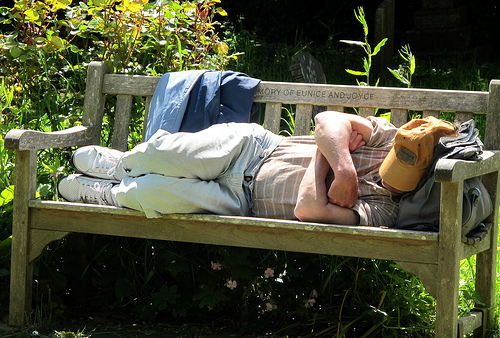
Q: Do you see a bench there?
A: Yes, there is a bench.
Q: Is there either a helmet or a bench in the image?
A: Yes, there is a bench.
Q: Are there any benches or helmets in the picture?
A: Yes, there is a bench.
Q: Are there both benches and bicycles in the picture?
A: No, there is a bench but no bicycles.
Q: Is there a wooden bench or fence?
A: Yes, there is a wood bench.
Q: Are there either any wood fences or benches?
A: Yes, there is a wood bench.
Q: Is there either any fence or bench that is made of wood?
A: Yes, the bench is made of wood.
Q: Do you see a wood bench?
A: Yes, there is a wood bench.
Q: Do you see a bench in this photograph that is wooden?
A: Yes, there is a bench that is wooden.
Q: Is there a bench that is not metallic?
A: Yes, there is a wooden bench.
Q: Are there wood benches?
A: Yes, there is a bench that is made of wood.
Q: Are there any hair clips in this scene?
A: No, there are no hair clips.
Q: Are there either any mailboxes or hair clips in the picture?
A: No, there are no hair clips or mailboxes.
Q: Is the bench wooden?
A: Yes, the bench is wooden.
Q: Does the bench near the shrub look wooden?
A: Yes, the bench is wooden.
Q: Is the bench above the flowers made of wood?
A: Yes, the bench is made of wood.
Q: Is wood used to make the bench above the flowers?
A: Yes, the bench is made of wood.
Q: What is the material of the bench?
A: The bench is made of wood.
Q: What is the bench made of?
A: The bench is made of wood.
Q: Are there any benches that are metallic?
A: No, there is a bench but it is wooden.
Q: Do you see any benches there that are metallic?
A: No, there is a bench but it is wooden.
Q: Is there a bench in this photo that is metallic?
A: No, there is a bench but it is wooden.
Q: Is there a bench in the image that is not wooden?
A: No, there is a bench but it is wooden.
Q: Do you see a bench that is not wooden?
A: No, there is a bench but it is wooden.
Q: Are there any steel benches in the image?
A: No, there is a bench but it is made of wood.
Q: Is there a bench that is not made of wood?
A: No, there is a bench but it is made of wood.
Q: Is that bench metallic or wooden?
A: The bench is wooden.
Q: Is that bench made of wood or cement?
A: The bench is made of wood.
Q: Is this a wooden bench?
A: Yes, this is a wooden bench.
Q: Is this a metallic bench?
A: No, this is a wooden bench.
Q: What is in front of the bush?
A: The bench is in front of the bush.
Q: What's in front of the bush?
A: The bench is in front of the bush.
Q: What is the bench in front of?
A: The bench is in front of the shrub.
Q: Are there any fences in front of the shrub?
A: No, there is a bench in front of the shrub.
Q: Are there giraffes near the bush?
A: No, there is a bench near the bush.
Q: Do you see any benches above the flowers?
A: Yes, there is a bench above the flowers.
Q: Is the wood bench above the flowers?
A: Yes, the bench is above the flowers.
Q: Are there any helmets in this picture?
A: No, there are no helmets.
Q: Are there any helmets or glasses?
A: No, there are no helmets or glasses.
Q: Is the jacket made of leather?
A: No, the jacket is made of denim.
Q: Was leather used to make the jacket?
A: No, the jacket is made of denim.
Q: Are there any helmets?
A: No, there are no helmets.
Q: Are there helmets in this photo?
A: No, there are no helmets.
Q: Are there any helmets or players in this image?
A: No, there are no helmets or players.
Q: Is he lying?
A: Yes, the man is lying.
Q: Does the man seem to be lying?
A: Yes, the man is lying.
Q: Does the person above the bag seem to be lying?
A: Yes, the man is lying.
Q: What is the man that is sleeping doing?
A: The man is lying.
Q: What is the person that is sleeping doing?
A: The man is lying.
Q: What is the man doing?
A: The man is lying.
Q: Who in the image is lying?
A: The man is lying.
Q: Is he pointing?
A: No, the man is lying.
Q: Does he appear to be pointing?
A: No, the man is lying.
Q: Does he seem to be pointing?
A: No, the man is lying.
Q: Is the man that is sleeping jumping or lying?
A: The man is lying.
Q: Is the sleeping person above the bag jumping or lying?
A: The man is lying.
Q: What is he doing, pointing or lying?
A: The man is lying.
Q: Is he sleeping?
A: Yes, the man is sleeping.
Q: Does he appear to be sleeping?
A: Yes, the man is sleeping.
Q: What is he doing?
A: The man is sleeping.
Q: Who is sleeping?
A: The man is sleeping.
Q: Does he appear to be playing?
A: No, the man is sleeping.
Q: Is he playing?
A: No, the man is sleeping.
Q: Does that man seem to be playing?
A: No, the man is sleeping.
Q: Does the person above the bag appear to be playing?
A: No, the man is sleeping.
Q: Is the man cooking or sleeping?
A: The man is sleeping.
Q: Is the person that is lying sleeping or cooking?
A: The man is sleeping.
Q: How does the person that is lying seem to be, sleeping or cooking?
A: The man is sleeping.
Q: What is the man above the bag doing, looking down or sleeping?
A: The man is sleeping.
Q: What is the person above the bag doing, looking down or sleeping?
A: The man is sleeping.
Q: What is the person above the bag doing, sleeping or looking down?
A: The man is sleeping.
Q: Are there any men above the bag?
A: Yes, there is a man above the bag.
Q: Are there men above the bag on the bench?
A: Yes, there is a man above the bag.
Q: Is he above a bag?
A: Yes, the man is above a bag.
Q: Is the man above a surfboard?
A: No, the man is above a bag.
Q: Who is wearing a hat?
A: The man is wearing a hat.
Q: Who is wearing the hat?
A: The man is wearing a hat.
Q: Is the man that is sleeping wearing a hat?
A: Yes, the man is wearing a hat.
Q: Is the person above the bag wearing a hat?
A: Yes, the man is wearing a hat.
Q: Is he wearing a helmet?
A: No, the man is wearing a hat.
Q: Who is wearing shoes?
A: The man is wearing shoes.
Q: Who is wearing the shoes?
A: The man is wearing shoes.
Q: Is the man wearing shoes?
A: Yes, the man is wearing shoes.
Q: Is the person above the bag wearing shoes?
A: Yes, the man is wearing shoes.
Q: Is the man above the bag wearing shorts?
A: No, the man is wearing shoes.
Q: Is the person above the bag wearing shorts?
A: No, the man is wearing shoes.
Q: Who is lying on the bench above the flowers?
A: The man is lying on the bench.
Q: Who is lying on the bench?
A: The man is lying on the bench.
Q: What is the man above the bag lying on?
A: The man is lying on the bench.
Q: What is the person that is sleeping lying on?
A: The man is lying on the bench.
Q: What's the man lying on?
A: The man is lying on the bench.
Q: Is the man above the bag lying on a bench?
A: Yes, the man is lying on a bench.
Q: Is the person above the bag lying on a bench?
A: Yes, the man is lying on a bench.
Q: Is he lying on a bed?
A: No, the man is lying on a bench.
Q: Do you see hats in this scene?
A: Yes, there is a hat.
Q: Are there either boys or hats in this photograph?
A: Yes, there is a hat.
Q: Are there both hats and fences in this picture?
A: No, there is a hat but no fences.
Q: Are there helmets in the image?
A: No, there are no helmets.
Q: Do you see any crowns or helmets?
A: No, there are no helmets or crowns.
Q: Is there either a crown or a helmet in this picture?
A: No, there are no helmets or crowns.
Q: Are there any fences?
A: No, there are no fences.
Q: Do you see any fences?
A: No, there are no fences.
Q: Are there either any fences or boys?
A: No, there are no fences or boys.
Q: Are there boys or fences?
A: No, there are no fences or boys.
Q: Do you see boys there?
A: No, there are no boys.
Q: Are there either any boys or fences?
A: No, there are no boys or fences.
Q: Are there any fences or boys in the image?
A: No, there are no boys or fences.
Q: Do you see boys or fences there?
A: No, there are no boys or fences.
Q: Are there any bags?
A: Yes, there is a bag.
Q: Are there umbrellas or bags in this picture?
A: Yes, there is a bag.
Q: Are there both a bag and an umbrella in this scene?
A: No, there is a bag but no umbrellas.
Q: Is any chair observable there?
A: No, there are no chairs.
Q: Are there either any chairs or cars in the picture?
A: No, there are no chairs or cars.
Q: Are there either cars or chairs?
A: No, there are no chairs or cars.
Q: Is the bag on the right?
A: Yes, the bag is on the right of the image.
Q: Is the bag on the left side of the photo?
A: No, the bag is on the right of the image.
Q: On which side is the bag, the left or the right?
A: The bag is on the right of the image.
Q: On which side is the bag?
A: The bag is on the right of the image.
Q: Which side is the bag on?
A: The bag is on the right of the image.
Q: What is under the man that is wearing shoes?
A: The bag is under the man.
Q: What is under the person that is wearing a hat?
A: The bag is under the man.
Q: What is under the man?
A: The bag is under the man.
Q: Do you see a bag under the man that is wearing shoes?
A: Yes, there is a bag under the man.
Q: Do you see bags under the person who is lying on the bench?
A: Yes, there is a bag under the man.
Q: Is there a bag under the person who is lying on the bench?
A: Yes, there is a bag under the man.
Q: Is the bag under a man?
A: Yes, the bag is under a man.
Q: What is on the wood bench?
A: The bag is on the bench.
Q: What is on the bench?
A: The bag is on the bench.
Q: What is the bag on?
A: The bag is on the bench.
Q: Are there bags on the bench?
A: Yes, there is a bag on the bench.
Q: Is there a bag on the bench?
A: Yes, there is a bag on the bench.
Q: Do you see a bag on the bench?
A: Yes, there is a bag on the bench.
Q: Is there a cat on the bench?
A: No, there is a bag on the bench.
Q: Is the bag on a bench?
A: Yes, the bag is on a bench.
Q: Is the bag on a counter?
A: No, the bag is on a bench.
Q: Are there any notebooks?
A: No, there are no notebooks.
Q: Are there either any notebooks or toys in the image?
A: No, there are no notebooks or toys.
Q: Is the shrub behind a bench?
A: Yes, the shrub is behind a bench.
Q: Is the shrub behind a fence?
A: No, the shrub is behind a bench.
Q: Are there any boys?
A: No, there are no boys.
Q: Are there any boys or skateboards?
A: No, there are no boys or skateboards.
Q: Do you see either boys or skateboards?
A: No, there are no boys or skateboards.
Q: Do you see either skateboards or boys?
A: No, there are no boys or skateboards.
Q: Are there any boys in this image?
A: No, there are no boys.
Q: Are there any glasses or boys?
A: No, there are no boys or glasses.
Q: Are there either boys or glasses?
A: No, there are no boys or glasses.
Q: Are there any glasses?
A: No, there are no glasses.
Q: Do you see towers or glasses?
A: No, there are no glasses or towers.